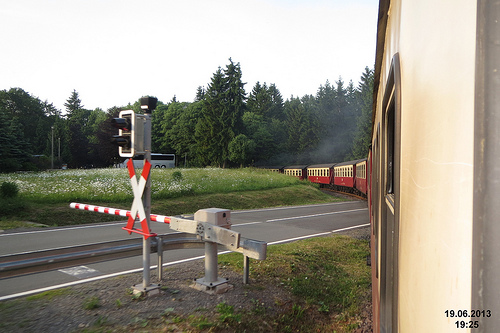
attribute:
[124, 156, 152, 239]
x — red, white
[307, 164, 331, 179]
frame — cream colored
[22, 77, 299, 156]
trees — green 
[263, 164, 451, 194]
train — long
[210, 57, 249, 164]
tree — green 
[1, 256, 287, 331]
dirt — light brown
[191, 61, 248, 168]
tree — green, tall, distant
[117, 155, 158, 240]
x — red , white 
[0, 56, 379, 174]
trees — green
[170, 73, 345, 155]
trees — green 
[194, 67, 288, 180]
trees — green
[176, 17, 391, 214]
trees — green 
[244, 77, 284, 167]
tree — green 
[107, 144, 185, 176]
bus — white 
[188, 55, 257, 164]
leaves — green